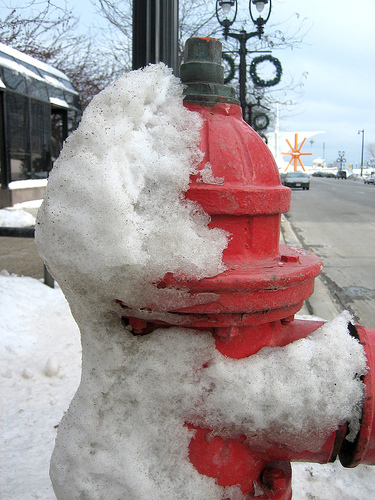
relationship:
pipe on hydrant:
[284, 314, 369, 445] [99, 86, 288, 463]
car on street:
[293, 169, 323, 193] [284, 199, 374, 291]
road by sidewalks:
[312, 196, 369, 281] [9, 170, 63, 229]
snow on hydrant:
[86, 340, 193, 459] [121, 73, 305, 455]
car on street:
[286, 169, 312, 193] [270, 214, 372, 305]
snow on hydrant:
[59, 135, 168, 276] [48, 108, 374, 496]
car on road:
[286, 169, 312, 193] [312, 196, 369, 281]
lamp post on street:
[348, 128, 373, 165] [305, 184, 369, 283]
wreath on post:
[246, 51, 292, 108] [228, 26, 260, 107]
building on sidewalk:
[3, 65, 131, 193] [0, 188, 55, 293]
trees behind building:
[19, 8, 173, 112] [3, 59, 71, 213]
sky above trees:
[223, 12, 368, 98] [9, 8, 119, 74]